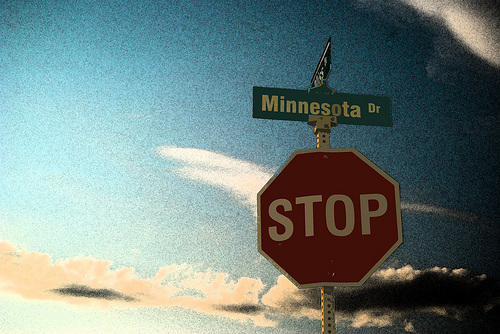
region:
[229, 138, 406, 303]
a red STOP sign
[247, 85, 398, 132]
the sign says Minnesota Dr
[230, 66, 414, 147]
the sign says Minnesota Dr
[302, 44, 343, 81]
a small green street sign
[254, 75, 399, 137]
a street sign for minnesota drive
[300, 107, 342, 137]
the end of a street pole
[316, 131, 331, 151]
a bunch of black holes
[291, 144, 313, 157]
the end of a stop sign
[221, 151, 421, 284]
a big red octogon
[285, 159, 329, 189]
the red of a stop sign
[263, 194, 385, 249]
the word stop written in white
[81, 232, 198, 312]
a bunch of white clouds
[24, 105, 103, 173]
the blue of the sky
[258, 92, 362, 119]
the word Minnesota on a street sign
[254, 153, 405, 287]
an octagonal stop sign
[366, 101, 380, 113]
the letters Dr on a sign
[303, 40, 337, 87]
a green sign for a cross street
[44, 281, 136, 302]
dark shading inside a white cloud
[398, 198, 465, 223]
a thin white line of a cloud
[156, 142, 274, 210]
part of a wispy white cloud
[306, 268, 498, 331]
a dark rain cloud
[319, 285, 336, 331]
metal pole beneath a stop sign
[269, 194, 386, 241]
the word STOP in white letters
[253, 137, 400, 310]
stop sign with the letter s on it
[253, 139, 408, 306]
stop sign with the letter t on it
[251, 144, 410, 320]
stop sign with the letter o on it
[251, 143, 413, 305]
stop sign with the letter p on it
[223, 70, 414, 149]
street sign with the letter m on it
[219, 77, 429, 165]
street sign with the letter i on it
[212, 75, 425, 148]
street sign with the letter n on it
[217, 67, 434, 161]
street sign with the letter e on it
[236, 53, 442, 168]
street sign with the letter s on it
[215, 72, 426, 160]
street sign with the letter o on it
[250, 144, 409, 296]
red stop sign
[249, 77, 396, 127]
green sign with white letters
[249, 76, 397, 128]
green sign saying Minnesota Dr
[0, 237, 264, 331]
white and grey clouds in the sky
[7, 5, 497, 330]
filtered photograph of street signs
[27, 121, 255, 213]
blue sky with white cloud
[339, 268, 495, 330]
dark grey and white clouds in the sky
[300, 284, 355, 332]
white metal sign post with holes in it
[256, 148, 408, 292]
red sign with white lettering saying STOP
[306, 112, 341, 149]
portion of white sign post